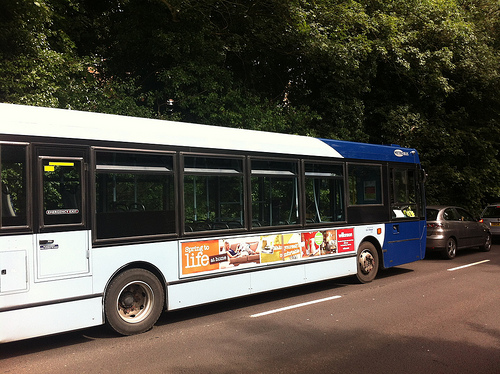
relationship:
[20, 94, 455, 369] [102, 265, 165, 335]
bus has tire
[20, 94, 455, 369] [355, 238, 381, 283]
bus has tire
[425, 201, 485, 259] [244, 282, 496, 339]
vehicles driving on road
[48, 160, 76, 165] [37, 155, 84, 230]
sticker on window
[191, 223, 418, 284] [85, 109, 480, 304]
sign on bus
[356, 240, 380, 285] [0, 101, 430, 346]
tire of a bus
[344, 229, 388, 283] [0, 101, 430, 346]
tire of a bus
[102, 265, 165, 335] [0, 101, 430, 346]
tire of bus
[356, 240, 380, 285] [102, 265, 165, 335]
tire of tire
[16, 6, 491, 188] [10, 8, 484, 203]
leaves on trees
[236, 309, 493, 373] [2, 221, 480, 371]
shadows on road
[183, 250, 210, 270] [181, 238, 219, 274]
life written on sign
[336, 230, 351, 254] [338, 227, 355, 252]
writing on sign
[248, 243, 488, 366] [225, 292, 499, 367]
stripes painted on road road